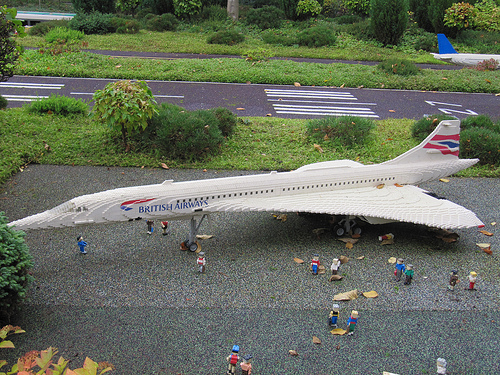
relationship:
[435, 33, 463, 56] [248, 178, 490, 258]
tail of plane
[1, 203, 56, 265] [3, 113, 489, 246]
nose on a plane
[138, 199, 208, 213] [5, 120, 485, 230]
logo on plane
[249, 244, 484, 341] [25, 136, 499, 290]
figures next to plane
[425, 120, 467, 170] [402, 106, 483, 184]
logo on tail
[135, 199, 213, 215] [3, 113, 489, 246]
british airways on plane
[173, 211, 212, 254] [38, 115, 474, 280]
landing gear on plane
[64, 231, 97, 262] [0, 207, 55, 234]
figurine under nose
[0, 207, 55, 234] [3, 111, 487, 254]
nose of airplane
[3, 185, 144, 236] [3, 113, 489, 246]
plane front on plane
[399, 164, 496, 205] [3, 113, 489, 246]
windows on plane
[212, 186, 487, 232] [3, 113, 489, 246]
wing on plane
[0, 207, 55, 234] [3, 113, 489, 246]
nose on plane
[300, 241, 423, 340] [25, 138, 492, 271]
people around plane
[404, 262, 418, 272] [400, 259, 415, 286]
head of person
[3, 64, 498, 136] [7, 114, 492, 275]
road near plane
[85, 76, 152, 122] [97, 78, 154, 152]
leaves on tree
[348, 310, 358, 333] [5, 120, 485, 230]
model spectator looking at plane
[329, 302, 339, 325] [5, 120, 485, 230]
model spectator looking at plane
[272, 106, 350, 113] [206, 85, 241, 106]
lines on asphalt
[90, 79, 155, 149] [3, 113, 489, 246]
bush standing behind plane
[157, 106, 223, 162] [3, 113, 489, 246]
bush standing behind plane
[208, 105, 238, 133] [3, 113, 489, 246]
bush standing behind plane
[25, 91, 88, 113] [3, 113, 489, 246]
bush standing behind plane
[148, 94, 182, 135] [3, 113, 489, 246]
bush standing behind plane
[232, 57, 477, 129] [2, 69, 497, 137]
lines on runway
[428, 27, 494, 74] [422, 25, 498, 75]
tail on plane